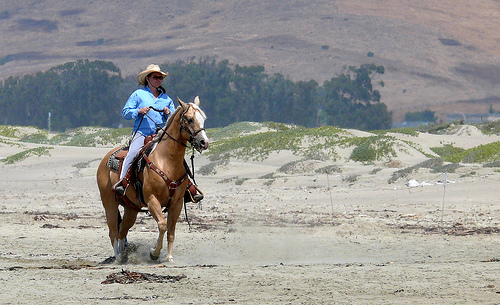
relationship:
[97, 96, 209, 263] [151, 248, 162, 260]
horse has a hoof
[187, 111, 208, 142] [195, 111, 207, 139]
face has a white shape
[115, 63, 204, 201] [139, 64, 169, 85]
woman has a hat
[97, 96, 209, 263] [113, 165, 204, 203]
horse has stirrups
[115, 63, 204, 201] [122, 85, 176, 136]
woman has a shirt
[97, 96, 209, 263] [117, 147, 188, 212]
horse has a harness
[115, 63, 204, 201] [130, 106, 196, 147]
woman holding onto reigns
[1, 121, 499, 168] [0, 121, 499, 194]
plants are on dunes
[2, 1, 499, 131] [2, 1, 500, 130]
clouds are in sky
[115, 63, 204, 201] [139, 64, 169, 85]
woman wearing a hat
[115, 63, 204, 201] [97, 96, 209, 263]
woman on horse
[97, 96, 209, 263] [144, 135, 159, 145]
horse has a saddle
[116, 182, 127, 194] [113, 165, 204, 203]
foot in stirrups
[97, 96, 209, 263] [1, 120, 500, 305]
horse in sand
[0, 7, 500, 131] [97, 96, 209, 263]
trees are behind horse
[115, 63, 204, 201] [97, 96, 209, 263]
woman riding horse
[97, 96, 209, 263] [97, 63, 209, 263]
horse being ridden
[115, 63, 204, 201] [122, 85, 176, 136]
woman wearing a shirt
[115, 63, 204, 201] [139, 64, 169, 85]
woman wearing hat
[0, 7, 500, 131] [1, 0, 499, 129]
trees are in background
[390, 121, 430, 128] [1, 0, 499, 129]
water in background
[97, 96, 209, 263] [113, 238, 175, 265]
horse has feet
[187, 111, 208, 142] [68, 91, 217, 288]
face of horse